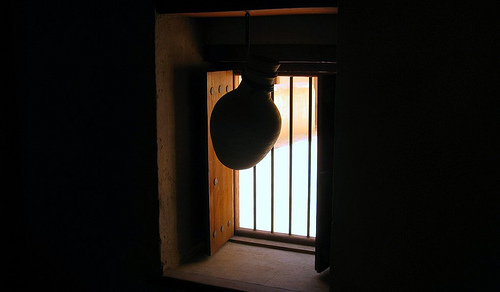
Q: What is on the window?
A: A metal grate.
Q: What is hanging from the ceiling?
A: A light.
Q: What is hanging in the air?
A: A clay vase.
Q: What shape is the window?
A: The window is square.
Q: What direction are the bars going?
A: Vertically.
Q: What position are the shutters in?
A: Open.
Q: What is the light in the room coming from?
A: The window.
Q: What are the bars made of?
A: Metal.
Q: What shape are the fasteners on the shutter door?
A: Round.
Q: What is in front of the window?
A: A pan.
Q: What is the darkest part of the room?
A: The walls.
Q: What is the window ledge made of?
A: Stone.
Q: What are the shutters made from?
A: Wood.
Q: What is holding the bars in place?
A: The window frame.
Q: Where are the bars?
A: On the outer window.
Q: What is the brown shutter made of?
A: Wood.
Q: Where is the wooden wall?
A: Left side of window.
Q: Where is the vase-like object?
A: Hanging in a window.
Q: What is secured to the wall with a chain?
A: A vase-like object.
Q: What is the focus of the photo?
A: A small outer wall window.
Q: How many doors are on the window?
A: 2.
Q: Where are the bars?
A: On window.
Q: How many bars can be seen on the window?
A: 4.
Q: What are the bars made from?
A: Metal.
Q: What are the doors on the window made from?
A: Wood.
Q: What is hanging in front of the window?
A: Jar.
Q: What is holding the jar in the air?
A: Rope.